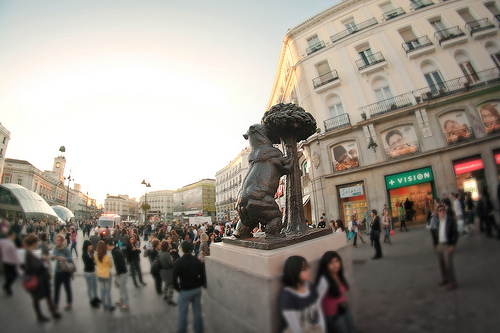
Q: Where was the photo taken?
A: It was taken at the walkway.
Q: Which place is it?
A: It is a walkway.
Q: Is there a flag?
A: No, there are no flags.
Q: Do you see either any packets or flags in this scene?
A: No, there are no flags or packets.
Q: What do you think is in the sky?
A: The clouds are in the sky.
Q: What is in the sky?
A: The clouds are in the sky.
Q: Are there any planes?
A: No, there are no planes.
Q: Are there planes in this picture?
A: No, there are no planes.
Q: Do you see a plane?
A: No, there are no airplanes.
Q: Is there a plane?
A: No, there are no airplanes.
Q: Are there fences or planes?
A: No, there are no planes or fences.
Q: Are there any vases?
A: No, there are no vases.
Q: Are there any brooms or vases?
A: No, there are no vases or brooms.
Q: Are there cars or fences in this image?
A: No, there are no fences or cars.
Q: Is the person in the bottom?
A: Yes, the person is in the bottom of the image.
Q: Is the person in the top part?
A: No, the person is in the bottom of the image.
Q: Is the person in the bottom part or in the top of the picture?
A: The person is in the bottom of the image.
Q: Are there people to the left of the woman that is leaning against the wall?
A: Yes, there is a person to the left of the woman.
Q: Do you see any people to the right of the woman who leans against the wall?
A: No, the person is to the left of the woman.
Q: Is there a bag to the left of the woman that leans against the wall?
A: No, there is a person to the left of the woman.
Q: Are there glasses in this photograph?
A: No, there are no glasses.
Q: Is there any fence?
A: No, there are no fences.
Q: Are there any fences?
A: No, there are no fences.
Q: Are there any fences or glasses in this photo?
A: No, there are no fences or glasses.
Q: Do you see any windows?
A: Yes, there is a window.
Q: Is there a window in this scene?
A: Yes, there is a window.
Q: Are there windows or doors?
A: Yes, there is a window.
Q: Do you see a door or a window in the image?
A: Yes, there is a window.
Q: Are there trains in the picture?
A: No, there are no trains.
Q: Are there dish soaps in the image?
A: No, there are no dish soaps.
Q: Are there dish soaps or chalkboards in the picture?
A: No, there are no dish soaps or chalkboards.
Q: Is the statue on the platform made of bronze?
A: Yes, the statue is made of bronze.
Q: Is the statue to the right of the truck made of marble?
A: No, the statue is made of bronze.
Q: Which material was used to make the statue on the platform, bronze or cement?
A: The statue is made of bronze.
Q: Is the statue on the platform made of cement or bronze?
A: The statue is made of bronze.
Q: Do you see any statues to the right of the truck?
A: Yes, there is a statue to the right of the truck.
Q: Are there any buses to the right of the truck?
A: No, there is a statue to the right of the truck.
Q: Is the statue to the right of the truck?
A: Yes, the statue is to the right of the truck.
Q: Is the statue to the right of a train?
A: No, the statue is to the right of the truck.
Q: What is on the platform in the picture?
A: The statue is on the platform.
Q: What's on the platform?
A: The statue is on the platform.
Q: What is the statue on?
A: The statue is on the platform.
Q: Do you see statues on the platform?
A: Yes, there is a statue on the platform.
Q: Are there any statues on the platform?
A: Yes, there is a statue on the platform.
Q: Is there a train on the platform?
A: No, there is a statue on the platform.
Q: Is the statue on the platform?
A: Yes, the statue is on the platform.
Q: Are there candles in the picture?
A: No, there are no candles.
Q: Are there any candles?
A: No, there are no candles.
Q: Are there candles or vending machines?
A: No, there are no candles or vending machines.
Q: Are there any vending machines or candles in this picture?
A: No, there are no candles or vending machines.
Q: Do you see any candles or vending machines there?
A: No, there are no candles or vending machines.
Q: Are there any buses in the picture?
A: No, there are no buses.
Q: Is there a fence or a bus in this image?
A: No, there are no buses or fences.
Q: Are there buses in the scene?
A: No, there are no buses.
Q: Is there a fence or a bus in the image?
A: No, there are no buses or fences.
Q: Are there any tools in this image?
A: No, there are no tools.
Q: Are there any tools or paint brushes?
A: No, there are no tools or paint brushes.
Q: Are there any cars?
A: No, there are no cars.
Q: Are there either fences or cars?
A: No, there are no cars or fences.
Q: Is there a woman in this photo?
A: Yes, there is a woman.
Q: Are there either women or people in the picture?
A: Yes, there is a woman.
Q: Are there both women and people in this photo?
A: Yes, there are both a woman and a person.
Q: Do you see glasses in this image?
A: No, there are no glasses.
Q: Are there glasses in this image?
A: No, there are no glasses.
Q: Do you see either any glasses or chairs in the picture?
A: No, there are no glasses or chairs.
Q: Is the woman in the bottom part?
A: Yes, the woman is in the bottom of the image.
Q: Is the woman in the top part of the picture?
A: No, the woman is in the bottom of the image.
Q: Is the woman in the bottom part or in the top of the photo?
A: The woman is in the bottom of the image.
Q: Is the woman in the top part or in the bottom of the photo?
A: The woman is in the bottom of the image.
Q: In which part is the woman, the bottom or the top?
A: The woman is in the bottom of the image.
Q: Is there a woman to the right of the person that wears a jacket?
A: Yes, there is a woman to the right of the person.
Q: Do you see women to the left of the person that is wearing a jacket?
A: No, the woman is to the right of the person.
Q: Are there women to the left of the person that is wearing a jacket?
A: No, the woman is to the right of the person.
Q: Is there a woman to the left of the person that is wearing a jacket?
A: No, the woman is to the right of the person.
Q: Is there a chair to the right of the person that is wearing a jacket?
A: No, there is a woman to the right of the person.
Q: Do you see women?
A: Yes, there is a woman.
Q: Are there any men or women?
A: Yes, there is a woman.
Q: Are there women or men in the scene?
A: Yes, there is a woman.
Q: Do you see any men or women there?
A: Yes, there is a woman.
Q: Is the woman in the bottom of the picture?
A: Yes, the woman is in the bottom of the image.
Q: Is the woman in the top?
A: No, the woman is in the bottom of the image.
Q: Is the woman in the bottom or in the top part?
A: The woman is in the bottom of the image.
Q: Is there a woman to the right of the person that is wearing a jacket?
A: Yes, there is a woman to the right of the person.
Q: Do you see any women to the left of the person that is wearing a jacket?
A: No, the woman is to the right of the person.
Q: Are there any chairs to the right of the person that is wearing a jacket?
A: No, there is a woman to the right of the person.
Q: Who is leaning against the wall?
A: The woman is leaning against the wall.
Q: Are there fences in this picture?
A: No, there are no fences.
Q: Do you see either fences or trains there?
A: No, there are no fences or trains.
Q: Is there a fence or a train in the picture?
A: No, there are no fences or trains.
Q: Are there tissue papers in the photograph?
A: No, there are no tissue papers.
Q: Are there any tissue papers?
A: No, there are no tissue papers.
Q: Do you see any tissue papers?
A: No, there are no tissue papers.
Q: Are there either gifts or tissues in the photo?
A: No, there are no tissues or gifts.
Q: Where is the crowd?
A: The crowd is on the walkway.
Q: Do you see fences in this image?
A: No, there are no fences.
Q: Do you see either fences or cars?
A: No, there are no fences or cars.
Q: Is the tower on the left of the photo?
A: Yes, the tower is on the left of the image.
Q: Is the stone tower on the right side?
A: No, the tower is on the left of the image.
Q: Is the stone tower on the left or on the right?
A: The tower is on the left of the image.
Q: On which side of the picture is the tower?
A: The tower is on the left of the image.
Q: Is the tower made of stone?
A: Yes, the tower is made of stone.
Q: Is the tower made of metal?
A: No, the tower is made of stone.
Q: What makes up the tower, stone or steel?
A: The tower is made of stone.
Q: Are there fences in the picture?
A: No, there are no fences.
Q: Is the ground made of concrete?
A: Yes, the ground is made of concrete.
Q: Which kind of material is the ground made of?
A: The ground is made of concrete.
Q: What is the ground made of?
A: The ground is made of concrete.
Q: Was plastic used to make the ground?
A: No, the ground is made of cement.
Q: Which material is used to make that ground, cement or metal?
A: The ground is made of cement.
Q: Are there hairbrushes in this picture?
A: No, there are no hairbrushes.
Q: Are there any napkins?
A: No, there are no napkins.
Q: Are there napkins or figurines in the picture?
A: No, there are no napkins or figurines.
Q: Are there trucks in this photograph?
A: Yes, there is a truck.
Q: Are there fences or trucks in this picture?
A: Yes, there is a truck.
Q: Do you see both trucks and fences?
A: No, there is a truck but no fences.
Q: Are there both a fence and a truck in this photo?
A: No, there is a truck but no fences.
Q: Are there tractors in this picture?
A: No, there are no tractors.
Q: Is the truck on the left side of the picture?
A: Yes, the truck is on the left of the image.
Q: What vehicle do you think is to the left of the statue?
A: The vehicle is a truck.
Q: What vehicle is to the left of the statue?
A: The vehicle is a truck.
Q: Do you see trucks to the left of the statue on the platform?
A: Yes, there is a truck to the left of the statue.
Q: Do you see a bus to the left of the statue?
A: No, there is a truck to the left of the statue.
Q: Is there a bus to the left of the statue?
A: No, there is a truck to the left of the statue.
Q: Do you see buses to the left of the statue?
A: No, there is a truck to the left of the statue.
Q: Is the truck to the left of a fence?
A: No, the truck is to the left of a statue.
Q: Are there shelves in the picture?
A: No, there are no shelves.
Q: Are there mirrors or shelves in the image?
A: No, there are no shelves or mirrors.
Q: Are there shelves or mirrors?
A: No, there are no shelves or mirrors.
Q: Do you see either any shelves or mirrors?
A: No, there are no shelves or mirrors.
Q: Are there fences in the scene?
A: No, there are no fences.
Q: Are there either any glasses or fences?
A: No, there are no fences or glasses.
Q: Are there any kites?
A: No, there are no kites.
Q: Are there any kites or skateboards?
A: No, there are no kites or skateboards.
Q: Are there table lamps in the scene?
A: No, there are no table lamps.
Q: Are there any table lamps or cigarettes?
A: No, there are no table lamps or cigarettes.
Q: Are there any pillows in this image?
A: No, there are no pillows.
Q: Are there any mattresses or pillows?
A: No, there are no pillows or mattresses.